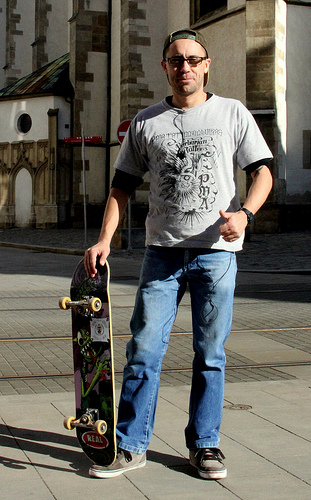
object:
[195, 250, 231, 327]
cord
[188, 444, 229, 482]
shoe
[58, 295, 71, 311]
wheel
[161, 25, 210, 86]
cap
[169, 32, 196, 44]
adjustable band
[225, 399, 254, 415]
grate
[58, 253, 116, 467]
skateboard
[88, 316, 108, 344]
white sticker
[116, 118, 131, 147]
sign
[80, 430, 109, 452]
sticker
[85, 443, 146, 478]
sneaker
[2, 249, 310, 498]
street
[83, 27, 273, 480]
man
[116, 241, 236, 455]
jeans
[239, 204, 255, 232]
watch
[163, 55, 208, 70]
glasses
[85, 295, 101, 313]
wheel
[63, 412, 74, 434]
wheel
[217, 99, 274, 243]
arm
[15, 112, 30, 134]
window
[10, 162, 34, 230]
door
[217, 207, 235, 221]
thumb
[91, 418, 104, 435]
wheel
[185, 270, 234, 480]
leg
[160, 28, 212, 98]
head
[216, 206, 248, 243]
hand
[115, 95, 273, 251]
shirt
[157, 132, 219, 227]
design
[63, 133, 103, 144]
sign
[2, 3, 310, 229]
building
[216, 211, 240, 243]
thumb up